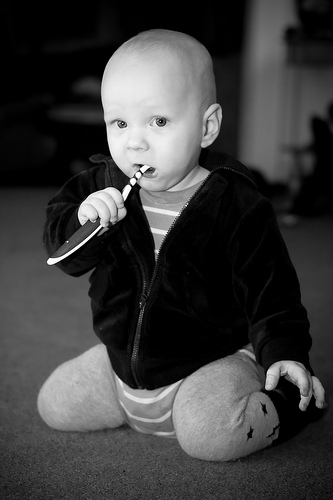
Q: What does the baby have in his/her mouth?
A: Toothbrush.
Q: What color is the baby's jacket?
A: Black.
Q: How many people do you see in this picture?
A: One.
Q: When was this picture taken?
A: During the day.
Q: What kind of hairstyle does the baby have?
A: Bald.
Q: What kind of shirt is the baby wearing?
A: Onesies.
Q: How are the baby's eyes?
A: Wide open.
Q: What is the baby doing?
A: Sitting down.